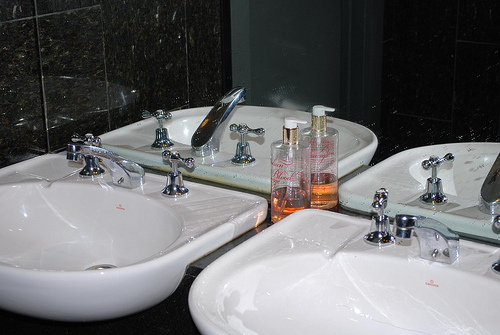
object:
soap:
[272, 188, 309, 214]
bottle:
[271, 117, 311, 224]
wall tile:
[0, 2, 123, 156]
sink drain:
[85, 264, 115, 272]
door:
[229, 1, 362, 114]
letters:
[116, 204, 126, 211]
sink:
[0, 151, 267, 324]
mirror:
[32, 2, 499, 248]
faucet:
[82, 144, 145, 189]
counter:
[0, 147, 500, 335]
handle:
[161, 149, 196, 198]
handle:
[69, 130, 102, 178]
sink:
[187, 207, 497, 335]